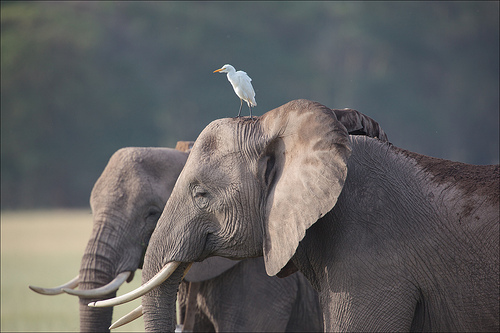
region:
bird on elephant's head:
[198, 42, 270, 144]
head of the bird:
[207, 62, 249, 87]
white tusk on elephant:
[76, 242, 204, 332]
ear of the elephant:
[236, 72, 390, 249]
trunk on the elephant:
[54, 217, 138, 329]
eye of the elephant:
[178, 164, 232, 221]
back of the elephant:
[393, 154, 478, 236]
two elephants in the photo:
[22, 39, 419, 314]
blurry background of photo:
[41, 25, 183, 115]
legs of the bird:
[222, 97, 268, 123]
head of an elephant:
[139, 100, 360, 287]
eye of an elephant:
[176, 162, 222, 211]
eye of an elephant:
[139, 190, 166, 225]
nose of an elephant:
[66, 260, 130, 328]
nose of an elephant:
[137, 280, 188, 331]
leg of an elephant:
[285, 270, 335, 325]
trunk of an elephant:
[96, 221, 179, 316]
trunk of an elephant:
[115, 305, 160, 330]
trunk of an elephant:
[72, 268, 137, 306]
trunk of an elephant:
[18, 274, 75, 309]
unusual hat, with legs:
[209, 59, 264, 127]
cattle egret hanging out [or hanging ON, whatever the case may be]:
[204, 57, 266, 132]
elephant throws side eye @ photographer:
[179, 171, 215, 213]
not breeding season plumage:
[202, 55, 268, 127]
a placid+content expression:
[139, 199, 169, 226]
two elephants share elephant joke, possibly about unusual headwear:
[17, 84, 356, 331]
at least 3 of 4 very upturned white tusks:
[12, 251, 178, 330]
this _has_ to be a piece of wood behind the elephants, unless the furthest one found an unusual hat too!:
[170, 136, 198, 156]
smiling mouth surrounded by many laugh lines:
[168, 201, 245, 266]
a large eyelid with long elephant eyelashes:
[189, 179, 209, 199]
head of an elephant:
[68, 118, 205, 263]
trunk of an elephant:
[52, 253, 157, 298]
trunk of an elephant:
[100, 270, 168, 315]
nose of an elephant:
[115, 256, 217, 328]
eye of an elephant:
[185, 179, 224, 205]